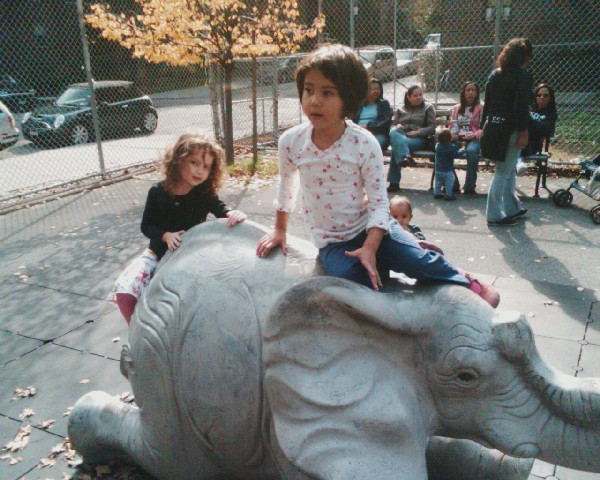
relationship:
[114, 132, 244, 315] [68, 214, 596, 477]
girl on elephant statue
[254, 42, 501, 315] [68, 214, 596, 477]
girl on elephant statue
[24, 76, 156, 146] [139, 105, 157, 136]
car has tire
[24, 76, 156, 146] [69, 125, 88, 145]
car has tire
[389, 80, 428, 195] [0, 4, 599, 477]
people on park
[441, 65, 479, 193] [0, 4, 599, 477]
woman on park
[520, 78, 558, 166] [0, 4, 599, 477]
person on park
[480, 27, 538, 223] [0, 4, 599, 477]
people on park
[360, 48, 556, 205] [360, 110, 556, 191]
people on bench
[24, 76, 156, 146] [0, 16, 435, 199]
car on street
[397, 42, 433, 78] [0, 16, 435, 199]
car on street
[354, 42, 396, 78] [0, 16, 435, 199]
car on street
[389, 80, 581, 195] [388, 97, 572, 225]
people on bench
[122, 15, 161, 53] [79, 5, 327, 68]
tree has leaves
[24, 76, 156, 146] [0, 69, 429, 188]
car on side of road